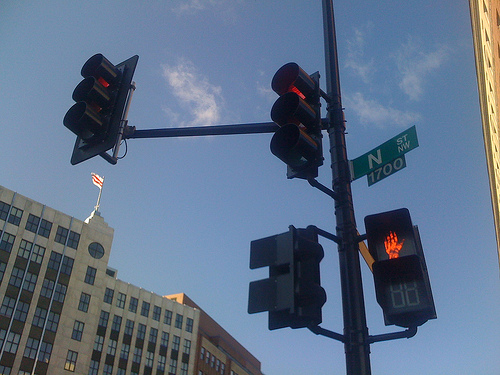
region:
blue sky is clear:
[116, 171, 265, 276]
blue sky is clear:
[132, 188, 237, 253]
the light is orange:
[366, 227, 408, 291]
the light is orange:
[375, 216, 426, 267]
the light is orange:
[366, 199, 419, 281]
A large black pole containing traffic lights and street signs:
[61, 0, 436, 373]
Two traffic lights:
[63, 52, 321, 177]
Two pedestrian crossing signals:
[247, 206, 437, 329]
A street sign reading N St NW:
[349, 123, 419, 185]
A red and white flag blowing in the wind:
[91, 172, 102, 187]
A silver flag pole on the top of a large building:
[95, 174, 103, 210]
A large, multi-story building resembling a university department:
[1, 185, 264, 373]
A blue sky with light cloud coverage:
[0, 1, 499, 373]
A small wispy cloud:
[161, 52, 226, 144]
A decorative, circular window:
[88, 240, 104, 257]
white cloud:
[169, 72, 222, 112]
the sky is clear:
[164, 199, 222, 236]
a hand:
[379, 227, 409, 260]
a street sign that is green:
[356, 145, 408, 158]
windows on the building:
[113, 318, 190, 360]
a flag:
[88, 173, 108, 187]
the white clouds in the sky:
[395, 49, 438, 96]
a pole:
[331, 137, 357, 204]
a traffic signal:
[71, 54, 132, 160]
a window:
[68, 323, 88, 339]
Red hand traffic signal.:
[367, 216, 417, 264]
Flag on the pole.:
[77, 168, 113, 211]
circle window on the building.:
[81, 236, 109, 264]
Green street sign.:
[344, 120, 422, 192]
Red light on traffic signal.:
[267, 58, 314, 103]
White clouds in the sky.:
[123, 23, 480, 150]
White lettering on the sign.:
[363, 130, 416, 171]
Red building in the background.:
[165, 288, 268, 373]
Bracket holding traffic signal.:
[305, 221, 351, 346]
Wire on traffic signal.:
[109, 132, 138, 164]